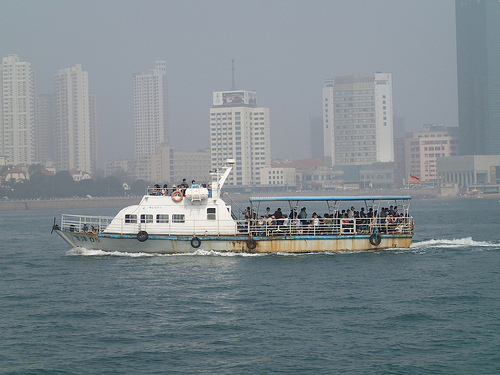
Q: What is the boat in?
A: Water.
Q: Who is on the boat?
A: A group of people.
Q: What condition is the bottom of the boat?
A: Rusted.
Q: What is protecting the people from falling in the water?
A: The railings.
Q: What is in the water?
A: A boat.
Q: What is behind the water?
A: Buidlings.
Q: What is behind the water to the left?
A: Trees.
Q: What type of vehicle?
A: Boat.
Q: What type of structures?
A: Buildings.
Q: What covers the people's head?
A: The blue shelter.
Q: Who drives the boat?
A: Captain.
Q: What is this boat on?
A: Water.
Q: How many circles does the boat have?
A: 5.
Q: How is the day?
A: Cloudy.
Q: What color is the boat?
A: White and blue.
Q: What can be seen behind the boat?
A: A city.